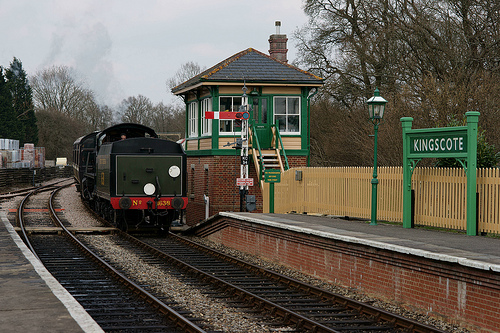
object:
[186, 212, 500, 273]
platform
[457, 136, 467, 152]
letter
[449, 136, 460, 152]
letter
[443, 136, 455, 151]
letter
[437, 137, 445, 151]
letter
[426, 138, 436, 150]
letter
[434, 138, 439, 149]
letter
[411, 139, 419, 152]
letter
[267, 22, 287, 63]
chimney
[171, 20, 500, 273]
train station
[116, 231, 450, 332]
tracks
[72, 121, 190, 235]
train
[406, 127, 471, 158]
sign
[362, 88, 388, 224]
light fixture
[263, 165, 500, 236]
fence